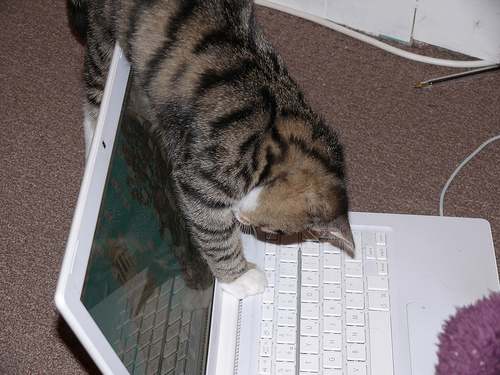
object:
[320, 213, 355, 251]
ear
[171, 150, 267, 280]
cat leg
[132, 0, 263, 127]
stripes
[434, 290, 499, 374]
object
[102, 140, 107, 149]
laptop cam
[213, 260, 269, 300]
paw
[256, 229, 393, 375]
keyboard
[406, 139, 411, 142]
ground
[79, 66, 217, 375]
computer screen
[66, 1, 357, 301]
cat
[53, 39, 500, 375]
computer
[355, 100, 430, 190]
carpet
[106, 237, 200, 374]
capitol building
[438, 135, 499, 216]
white cord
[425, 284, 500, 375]
toy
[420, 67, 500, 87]
pen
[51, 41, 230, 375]
lid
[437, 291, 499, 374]
fabric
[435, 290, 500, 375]
cloth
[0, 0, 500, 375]
floor